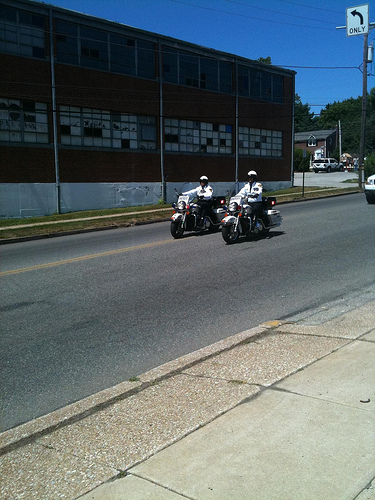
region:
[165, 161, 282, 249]
Two police man riding bikes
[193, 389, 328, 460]
Side walk near the road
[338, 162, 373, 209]
A car running on the road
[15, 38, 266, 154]
Building near the road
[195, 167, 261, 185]
Peoples wearing white color helmet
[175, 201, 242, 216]
Head lights with side indicators of the bike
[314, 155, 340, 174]
A car parked near the home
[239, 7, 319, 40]
A blue color sky with clouds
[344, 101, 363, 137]
Tree near the house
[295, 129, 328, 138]
Roof of the house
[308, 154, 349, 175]
white colored SUV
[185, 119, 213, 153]
white windows that are broken in building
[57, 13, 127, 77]
either opened or broken windows in building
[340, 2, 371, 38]
left turn only white street sign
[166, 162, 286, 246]
two police officers on bikes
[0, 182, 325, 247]
grassy curb along street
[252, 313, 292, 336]
yellow ainted edge of curb next to driveway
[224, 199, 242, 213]
motorcycle headlight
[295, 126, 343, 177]
brown two story home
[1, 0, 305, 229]
three story brown and gray old brick building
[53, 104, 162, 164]
broken windows on building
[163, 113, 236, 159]
broken windows on building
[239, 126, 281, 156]
broken windows on building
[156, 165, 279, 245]
two police officers on motorcycles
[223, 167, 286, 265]
police officer on motorcycle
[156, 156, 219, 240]
police officer on motorcycle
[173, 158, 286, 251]
two motorcycles on the road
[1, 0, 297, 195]
large abandoned building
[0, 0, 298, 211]
abandoned building with broken windows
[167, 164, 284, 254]
two men on motorcycles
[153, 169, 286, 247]
pair of cops on motorcyles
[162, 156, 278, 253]
two policemen on motorcycles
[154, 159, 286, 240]
policemen riding motorcycles on road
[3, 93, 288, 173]
warehouse with broken out windows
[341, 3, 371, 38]
white and black turn only sign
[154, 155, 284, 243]
motorcycle cops wearing helmets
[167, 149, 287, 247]
cops on motorcycles with white helmets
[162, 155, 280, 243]
two policemen on their motorcycles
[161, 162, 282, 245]
a policeman riding his motorcycle with partner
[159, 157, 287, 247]
two police officers riding motorcycles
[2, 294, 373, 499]
grey cement sidewalk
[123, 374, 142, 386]
patch of grass on curb of sidewalk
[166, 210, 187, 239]
front black wheel of motorcycle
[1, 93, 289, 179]
windows on side of brick building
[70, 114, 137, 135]
broken windows on side of brick building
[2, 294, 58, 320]
dark stain on street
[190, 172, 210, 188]
white helmet on officer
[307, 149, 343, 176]
white suv parked in parking lot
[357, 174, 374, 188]
one headlight on front of vehicle